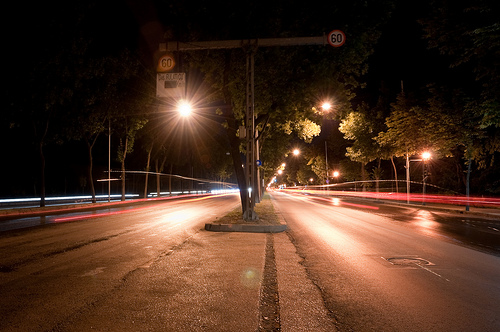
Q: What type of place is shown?
A: It is a street.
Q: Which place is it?
A: It is a street.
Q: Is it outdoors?
A: Yes, it is outdoors.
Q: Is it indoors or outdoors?
A: It is outdoors.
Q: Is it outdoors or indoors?
A: It is outdoors.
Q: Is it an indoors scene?
A: No, it is outdoors.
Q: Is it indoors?
A: No, it is outdoors.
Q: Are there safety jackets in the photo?
A: No, there are no safety jackets.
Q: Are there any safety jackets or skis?
A: No, there are no safety jackets or skis.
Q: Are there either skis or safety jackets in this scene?
A: No, there are no safety jackets or skis.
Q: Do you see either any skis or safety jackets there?
A: No, there are no safety jackets or skis.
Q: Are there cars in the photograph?
A: No, there are no cars.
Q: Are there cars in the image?
A: No, there are no cars.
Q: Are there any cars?
A: No, there are no cars.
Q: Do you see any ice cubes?
A: No, there are no ice cubes.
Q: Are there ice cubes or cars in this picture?
A: No, there are no ice cubes or cars.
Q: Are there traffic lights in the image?
A: No, there are no traffic lights.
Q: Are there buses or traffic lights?
A: No, there are no traffic lights or buses.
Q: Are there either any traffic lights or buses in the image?
A: No, there are no traffic lights or buses.